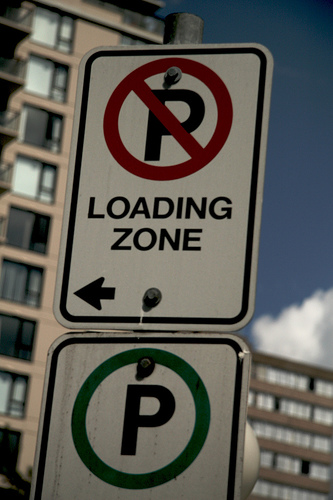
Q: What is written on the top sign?
A: Loading zone.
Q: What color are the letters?
A: Black.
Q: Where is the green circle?
A: On the bottom sign.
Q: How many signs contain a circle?
A: Two.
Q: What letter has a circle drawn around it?
A: P.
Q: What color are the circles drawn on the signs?
A: Red and green.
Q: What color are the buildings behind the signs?
A: Brown.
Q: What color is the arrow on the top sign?
A: Black.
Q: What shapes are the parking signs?
A: Rectangular.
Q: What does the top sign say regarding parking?
A: No parking allowed.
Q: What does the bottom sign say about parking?
A: Parking is allowed.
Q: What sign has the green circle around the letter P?
A: Bottom sign.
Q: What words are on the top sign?
A: Loading Zone.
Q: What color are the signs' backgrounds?
A: White.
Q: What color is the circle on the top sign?
A: Red.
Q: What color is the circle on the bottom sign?
A: Green.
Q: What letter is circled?
A: P.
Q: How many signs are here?
A: Two.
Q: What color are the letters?
A: Black.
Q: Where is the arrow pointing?
A: To the left.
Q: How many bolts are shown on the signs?
A: Three.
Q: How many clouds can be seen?
A: One.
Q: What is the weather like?
A: Sunny.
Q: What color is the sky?
A: Blue.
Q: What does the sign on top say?
A: Loading zone.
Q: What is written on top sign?
A: Loading zone.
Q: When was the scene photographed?
A: During the day.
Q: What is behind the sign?
A: A very tall building.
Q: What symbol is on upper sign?
A: P with circle drawn around it and line through it.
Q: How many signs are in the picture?
A: 2.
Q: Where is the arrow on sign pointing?
A: Left.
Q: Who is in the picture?
A: No one.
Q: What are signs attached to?
A: A pole.